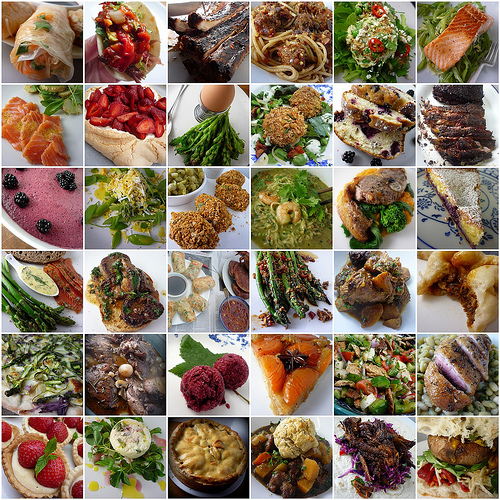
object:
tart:
[2, 432, 70, 499]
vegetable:
[251, 85, 332, 167]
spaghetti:
[252, 0, 332, 84]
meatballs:
[277, 34, 330, 76]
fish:
[422, 3, 494, 70]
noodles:
[418, 1, 491, 83]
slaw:
[334, 3, 416, 82]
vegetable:
[84, 416, 165, 493]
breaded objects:
[169, 210, 221, 249]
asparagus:
[290, 250, 318, 307]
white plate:
[251, 252, 331, 331]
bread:
[333, 84, 415, 160]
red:
[109, 104, 118, 114]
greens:
[417, 1, 492, 84]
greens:
[332, 1, 416, 82]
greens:
[168, 106, 246, 166]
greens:
[33, 84, 81, 116]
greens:
[382, 204, 407, 234]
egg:
[200, 85, 235, 112]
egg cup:
[193, 103, 221, 124]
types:
[3, 2, 495, 498]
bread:
[6, 250, 66, 264]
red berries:
[180, 365, 230, 413]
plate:
[167, 335, 249, 416]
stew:
[251, 417, 332, 496]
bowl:
[250, 418, 334, 498]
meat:
[178, 1, 249, 85]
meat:
[418, 84, 496, 165]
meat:
[424, 334, 492, 413]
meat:
[332, 418, 416, 499]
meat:
[337, 167, 416, 242]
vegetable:
[335, 4, 352, 89]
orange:
[251, 333, 333, 415]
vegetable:
[86, 168, 164, 247]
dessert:
[2, 168, 83, 250]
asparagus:
[267, 251, 291, 325]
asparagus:
[253, 250, 288, 327]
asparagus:
[281, 251, 305, 318]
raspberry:
[14, 192, 30, 209]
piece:
[433, 83, 483, 103]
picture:
[0, 0, 498, 498]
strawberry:
[18, 440, 66, 486]